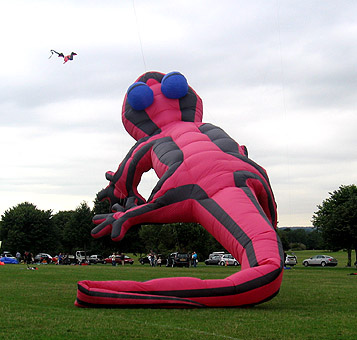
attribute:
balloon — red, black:
[101, 66, 306, 323]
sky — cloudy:
[0, 3, 353, 226]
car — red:
[101, 252, 135, 265]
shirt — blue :
[193, 253, 198, 258]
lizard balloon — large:
[67, 58, 313, 313]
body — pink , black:
[126, 71, 248, 234]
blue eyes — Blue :
[124, 69, 191, 108]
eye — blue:
[115, 69, 205, 113]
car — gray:
[301, 253, 339, 268]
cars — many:
[2, 249, 335, 269]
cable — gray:
[155, 322, 196, 339]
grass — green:
[1, 248, 353, 339]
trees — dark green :
[2, 203, 181, 257]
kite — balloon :
[40, 33, 89, 68]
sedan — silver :
[304, 255, 335, 266]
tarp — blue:
[5, 251, 13, 260]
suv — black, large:
[140, 244, 232, 282]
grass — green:
[4, 263, 355, 338]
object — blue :
[2, 251, 18, 266]